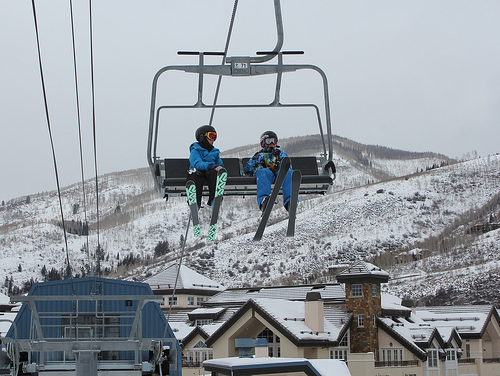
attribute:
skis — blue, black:
[185, 169, 225, 241]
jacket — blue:
[248, 150, 290, 172]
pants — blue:
[256, 166, 294, 208]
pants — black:
[190, 167, 220, 203]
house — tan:
[204, 267, 464, 375]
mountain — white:
[1, 132, 498, 305]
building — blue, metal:
[5, 279, 181, 356]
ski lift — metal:
[152, 67, 337, 198]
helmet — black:
[260, 130, 278, 148]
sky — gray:
[3, 4, 499, 202]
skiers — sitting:
[183, 127, 303, 242]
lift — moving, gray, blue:
[4, 296, 175, 373]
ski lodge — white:
[208, 259, 500, 375]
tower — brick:
[346, 281, 381, 350]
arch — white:
[230, 317, 282, 359]